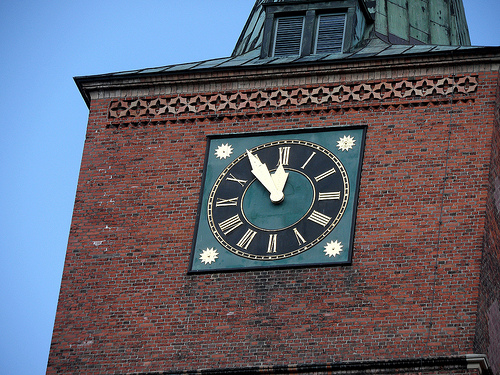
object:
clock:
[189, 126, 365, 273]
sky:
[0, 0, 251, 77]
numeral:
[277, 146, 291, 166]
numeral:
[300, 151, 317, 169]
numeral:
[314, 167, 337, 182]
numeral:
[318, 191, 341, 202]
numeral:
[308, 209, 332, 227]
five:
[292, 228, 308, 246]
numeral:
[266, 233, 279, 254]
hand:
[243, 149, 280, 201]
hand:
[268, 162, 291, 190]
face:
[207, 139, 350, 260]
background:
[0, 0, 500, 375]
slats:
[318, 14, 344, 34]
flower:
[213, 142, 234, 159]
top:
[205, 128, 363, 148]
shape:
[337, 134, 357, 152]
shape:
[324, 240, 344, 257]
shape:
[199, 247, 220, 265]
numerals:
[226, 173, 248, 187]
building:
[43, 0, 499, 375]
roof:
[83, 41, 500, 76]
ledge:
[78, 53, 499, 91]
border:
[186, 125, 368, 275]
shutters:
[270, 8, 347, 53]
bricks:
[381, 118, 470, 154]